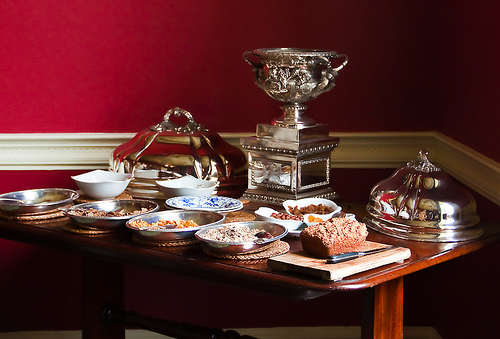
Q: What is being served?
A: Sweets.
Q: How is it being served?
A: Buffet-style.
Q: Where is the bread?
A: Sitting on the cutting board.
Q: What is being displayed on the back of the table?
A: Silver pieces.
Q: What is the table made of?
A: Wood.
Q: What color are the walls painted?
A: Red.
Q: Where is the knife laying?
A: Next to the bread.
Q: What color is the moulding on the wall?
A: White.